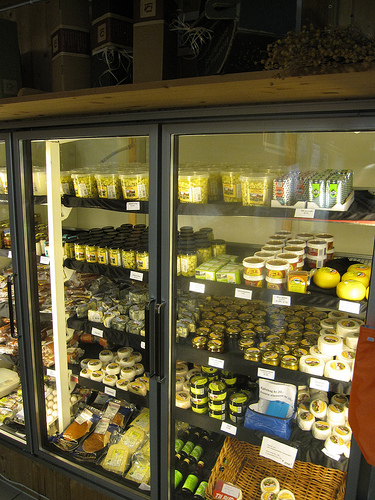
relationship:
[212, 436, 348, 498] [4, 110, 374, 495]
basket in bottom of cooler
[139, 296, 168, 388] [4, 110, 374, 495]
handles on cooler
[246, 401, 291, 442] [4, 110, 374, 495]
pouch in cooler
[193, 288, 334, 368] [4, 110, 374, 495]
jars in cooler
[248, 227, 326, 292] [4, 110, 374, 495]
container inside cooler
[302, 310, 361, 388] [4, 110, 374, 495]
goods inside cooler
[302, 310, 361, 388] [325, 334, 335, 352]
goods wrapped in plastic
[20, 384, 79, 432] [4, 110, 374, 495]
eggs inside cooler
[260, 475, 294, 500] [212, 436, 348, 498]
items in basket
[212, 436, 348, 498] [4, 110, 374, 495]
basket inside cooler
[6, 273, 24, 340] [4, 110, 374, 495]
handle on cooler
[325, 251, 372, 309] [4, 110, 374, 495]
cheese inside cooler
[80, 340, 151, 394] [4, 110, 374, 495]
cheese inside cooler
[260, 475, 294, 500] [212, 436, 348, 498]
cheese in basket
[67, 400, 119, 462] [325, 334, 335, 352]
sandwiches wrapped in plastic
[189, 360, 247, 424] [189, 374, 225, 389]
jars with lids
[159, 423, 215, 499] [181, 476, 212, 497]
bottles with labels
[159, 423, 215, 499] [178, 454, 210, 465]
bottles with lids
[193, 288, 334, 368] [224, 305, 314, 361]
jars with lids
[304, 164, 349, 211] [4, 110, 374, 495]
boxes inside cooler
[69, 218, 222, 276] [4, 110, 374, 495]
bottles inside cooler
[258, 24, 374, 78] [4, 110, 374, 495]
flowers on top of cooler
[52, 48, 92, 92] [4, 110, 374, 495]
box on top of cooler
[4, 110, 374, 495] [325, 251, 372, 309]
cooler has cheese